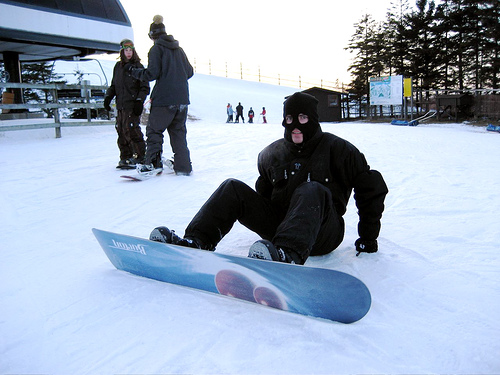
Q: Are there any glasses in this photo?
A: No, there are no glasses.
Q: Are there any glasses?
A: No, there are no glasses.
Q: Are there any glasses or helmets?
A: No, there are no glasses or helmets.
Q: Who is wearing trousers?
A: The man is wearing trousers.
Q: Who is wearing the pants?
A: The man is wearing trousers.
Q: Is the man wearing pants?
A: Yes, the man is wearing pants.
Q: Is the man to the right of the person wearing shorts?
A: No, the man is wearing pants.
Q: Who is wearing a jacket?
A: The man is wearing a jacket.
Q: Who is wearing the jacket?
A: The man is wearing a jacket.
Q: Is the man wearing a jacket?
A: Yes, the man is wearing a jacket.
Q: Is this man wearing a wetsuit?
A: No, the man is wearing a jacket.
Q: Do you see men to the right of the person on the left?
A: Yes, there is a man to the right of the person.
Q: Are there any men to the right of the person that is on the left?
A: Yes, there is a man to the right of the person.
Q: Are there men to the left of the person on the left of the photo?
A: No, the man is to the right of the person.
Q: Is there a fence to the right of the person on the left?
A: No, there is a man to the right of the person.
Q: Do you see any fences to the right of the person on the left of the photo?
A: No, there is a man to the right of the person.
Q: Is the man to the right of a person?
A: Yes, the man is to the right of a person.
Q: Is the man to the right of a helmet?
A: No, the man is to the right of a person.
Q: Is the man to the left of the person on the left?
A: No, the man is to the right of the person.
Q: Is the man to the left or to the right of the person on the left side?
A: The man is to the right of the person.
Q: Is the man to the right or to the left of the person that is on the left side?
A: The man is to the right of the person.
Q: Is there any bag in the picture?
A: No, there are no bags.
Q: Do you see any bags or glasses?
A: No, there are no bags or glasses.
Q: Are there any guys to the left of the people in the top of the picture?
A: Yes, there is a guy to the left of the people.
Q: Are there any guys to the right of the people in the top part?
A: No, the guy is to the left of the people.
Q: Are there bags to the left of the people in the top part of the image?
A: No, there is a guy to the left of the people.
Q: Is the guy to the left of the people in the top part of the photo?
A: Yes, the guy is to the left of the people.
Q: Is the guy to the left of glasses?
A: No, the guy is to the left of the people.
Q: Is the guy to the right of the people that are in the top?
A: No, the guy is to the left of the people.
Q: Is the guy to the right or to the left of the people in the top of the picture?
A: The guy is to the left of the people.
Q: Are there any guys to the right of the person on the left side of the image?
A: Yes, there is a guy to the right of the person.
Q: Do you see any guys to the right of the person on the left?
A: Yes, there is a guy to the right of the person.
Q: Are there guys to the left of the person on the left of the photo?
A: No, the guy is to the right of the person.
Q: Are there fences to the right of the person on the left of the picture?
A: No, there is a guy to the right of the person.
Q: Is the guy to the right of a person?
A: Yes, the guy is to the right of a person.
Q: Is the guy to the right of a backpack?
A: No, the guy is to the right of a person.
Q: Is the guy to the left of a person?
A: No, the guy is to the right of a person.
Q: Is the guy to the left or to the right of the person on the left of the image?
A: The guy is to the right of the person.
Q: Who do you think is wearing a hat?
A: The guy is wearing a hat.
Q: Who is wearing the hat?
A: The guy is wearing a hat.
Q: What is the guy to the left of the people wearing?
A: The guy is wearing a hat.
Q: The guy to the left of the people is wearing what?
A: The guy is wearing a hat.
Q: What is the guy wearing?
A: The guy is wearing a hat.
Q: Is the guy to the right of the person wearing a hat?
A: Yes, the guy is wearing a hat.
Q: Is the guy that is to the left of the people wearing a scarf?
A: No, the guy is wearing a hat.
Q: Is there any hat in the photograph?
A: Yes, there is a hat.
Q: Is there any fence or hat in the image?
A: Yes, there is a hat.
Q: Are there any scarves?
A: No, there are no scarves.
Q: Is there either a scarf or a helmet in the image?
A: No, there are no scarves or helmets.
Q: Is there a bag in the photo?
A: No, there are no bags.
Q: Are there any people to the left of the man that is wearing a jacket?
A: Yes, there is a person to the left of the man.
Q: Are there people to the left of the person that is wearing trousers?
A: Yes, there is a person to the left of the man.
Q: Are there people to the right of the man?
A: No, the person is to the left of the man.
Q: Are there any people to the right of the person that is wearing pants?
A: No, the person is to the left of the man.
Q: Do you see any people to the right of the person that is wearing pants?
A: No, the person is to the left of the man.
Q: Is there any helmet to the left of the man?
A: No, there is a person to the left of the man.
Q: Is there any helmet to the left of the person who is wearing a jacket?
A: No, there is a person to the left of the man.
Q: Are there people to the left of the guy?
A: Yes, there is a person to the left of the guy.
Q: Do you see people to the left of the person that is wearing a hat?
A: Yes, there is a person to the left of the guy.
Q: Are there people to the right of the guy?
A: No, the person is to the left of the guy.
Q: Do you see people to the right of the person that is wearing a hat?
A: No, the person is to the left of the guy.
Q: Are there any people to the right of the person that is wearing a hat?
A: No, the person is to the left of the guy.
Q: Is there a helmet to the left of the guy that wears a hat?
A: No, there is a person to the left of the guy.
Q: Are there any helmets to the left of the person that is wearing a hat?
A: No, there is a person to the left of the guy.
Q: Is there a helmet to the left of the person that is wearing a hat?
A: No, there is a person to the left of the guy.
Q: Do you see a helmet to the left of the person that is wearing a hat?
A: No, there is a person to the left of the guy.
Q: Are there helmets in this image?
A: No, there are no helmets.